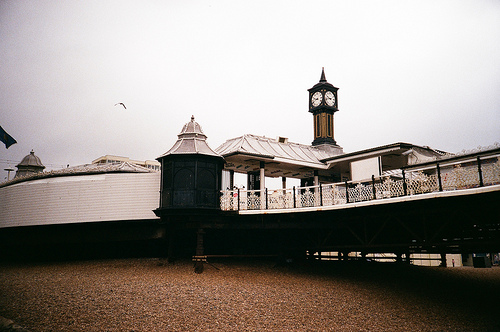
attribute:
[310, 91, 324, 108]
clock — brown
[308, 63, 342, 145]
tower — small, black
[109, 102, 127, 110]
bird — flying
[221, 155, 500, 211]
fence — white, chain link, short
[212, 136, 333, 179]
roof — white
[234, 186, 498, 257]
bridge — black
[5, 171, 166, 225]
wall — bricked, white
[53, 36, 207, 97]
sky — clear, white, grey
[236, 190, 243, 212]
pole — short